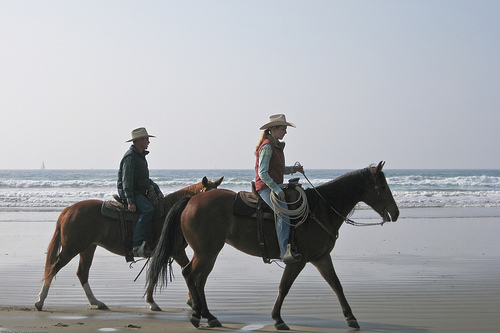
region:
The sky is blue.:
[210, 46, 384, 111]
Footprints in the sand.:
[46, 310, 144, 332]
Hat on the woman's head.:
[247, 107, 311, 146]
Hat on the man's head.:
[112, 116, 177, 166]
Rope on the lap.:
[258, 185, 321, 228]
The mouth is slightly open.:
[356, 203, 406, 229]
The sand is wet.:
[376, 239, 485, 281]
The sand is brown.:
[0, 301, 125, 332]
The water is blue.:
[168, 161, 262, 184]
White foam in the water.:
[418, 165, 499, 200]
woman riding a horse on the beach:
[143, 111, 400, 331]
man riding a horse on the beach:
[31, 126, 225, 315]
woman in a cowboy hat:
[252, 109, 298, 153]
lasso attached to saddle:
[267, 178, 309, 229]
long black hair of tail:
[142, 197, 189, 299]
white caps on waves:
[390, 171, 494, 188]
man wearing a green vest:
[115, 146, 154, 198]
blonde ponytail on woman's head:
[251, 125, 272, 152]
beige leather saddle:
[100, 196, 150, 265]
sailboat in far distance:
[37, 158, 47, 171]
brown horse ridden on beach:
[185, 167, 394, 321]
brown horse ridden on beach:
[41, 195, 224, 258]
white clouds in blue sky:
[19, 13, 106, 70]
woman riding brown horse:
[253, 106, 297, 216]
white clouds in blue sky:
[13, 58, 67, 102]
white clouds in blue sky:
[89, 12, 174, 65]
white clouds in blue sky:
[75, 64, 146, 117]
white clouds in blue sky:
[188, 20, 308, 100]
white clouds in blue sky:
[341, 15, 452, 76]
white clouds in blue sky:
[340, 93, 449, 146]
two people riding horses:
[26, 119, 431, 324]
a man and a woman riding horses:
[85, 95, 401, 252]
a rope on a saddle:
[266, 173, 318, 230]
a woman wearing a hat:
[266, 98, 301, 147]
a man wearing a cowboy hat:
[123, 119, 165, 168]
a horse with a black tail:
[142, 163, 400, 302]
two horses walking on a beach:
[35, 176, 413, 311]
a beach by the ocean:
[416, 162, 491, 282]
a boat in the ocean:
[35, 156, 65, 179]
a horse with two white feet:
[28, 249, 105, 324]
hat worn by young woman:
[257, 105, 299, 132]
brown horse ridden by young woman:
[194, 157, 400, 327]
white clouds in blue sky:
[7, 13, 61, 55]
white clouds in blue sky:
[35, 66, 81, 106]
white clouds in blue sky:
[32, 87, 90, 140]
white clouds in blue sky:
[163, 95, 242, 161]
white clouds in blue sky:
[194, 14, 279, 59]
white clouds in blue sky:
[332, 21, 400, 96]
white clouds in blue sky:
[410, 88, 458, 149]